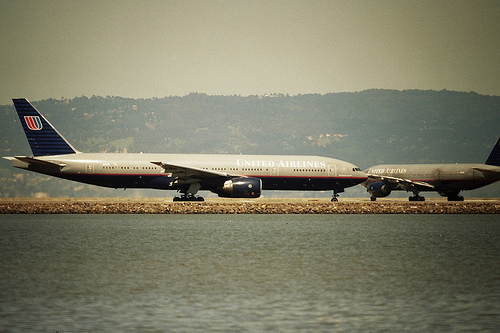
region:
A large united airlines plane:
[360, 140, 497, 200]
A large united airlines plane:
[1, 96, 367, 204]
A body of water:
[3, 211, 496, 331]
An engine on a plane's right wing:
[218, 175, 262, 200]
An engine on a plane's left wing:
[367, 177, 389, 200]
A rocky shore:
[2, 200, 499, 212]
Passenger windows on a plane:
[99, 163, 329, 173]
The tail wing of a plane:
[1, 99, 81, 191]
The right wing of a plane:
[151, 161, 245, 192]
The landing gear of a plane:
[169, 193, 339, 202]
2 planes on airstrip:
[3, 67, 491, 276]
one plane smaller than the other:
[0, 65, 492, 242]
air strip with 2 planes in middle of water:
[2, 3, 499, 261]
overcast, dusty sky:
[1, 0, 496, 200]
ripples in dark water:
[1, 203, 475, 330]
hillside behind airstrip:
[3, 63, 487, 195]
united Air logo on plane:
[16, 98, 91, 173]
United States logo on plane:
[369, 153, 422, 190]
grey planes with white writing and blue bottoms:
[3, 65, 498, 282]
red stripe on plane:
[0, 68, 373, 242]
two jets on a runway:
[5, 67, 485, 242]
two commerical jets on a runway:
[0, 85, 491, 210]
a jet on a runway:
[0, 88, 367, 206]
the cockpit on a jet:
[346, 160, 361, 176]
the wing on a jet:
[147, 160, 250, 177]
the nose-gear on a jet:
[326, 185, 348, 202]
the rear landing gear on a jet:
[167, 181, 207, 203]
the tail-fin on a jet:
[6, 91, 81, 153]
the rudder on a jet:
[15, 105, 35, 153]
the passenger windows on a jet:
[288, 165, 332, 175]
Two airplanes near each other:
[3, 95, 498, 207]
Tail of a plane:
[10, 93, 77, 155]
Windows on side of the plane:
[291, 160, 326, 177]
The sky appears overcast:
[1, 0, 497, 98]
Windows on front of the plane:
[349, 160, 363, 180]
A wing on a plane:
[150, 153, 230, 194]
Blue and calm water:
[1, 212, 499, 330]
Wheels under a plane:
[164, 190, 206, 209]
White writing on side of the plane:
[363, 162, 411, 182]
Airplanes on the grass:
[1, 183, 499, 214]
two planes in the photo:
[23, 90, 490, 257]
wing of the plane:
[151, 145, 235, 204]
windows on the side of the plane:
[233, 160, 338, 179]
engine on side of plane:
[221, 168, 268, 213]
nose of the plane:
[335, 148, 380, 202]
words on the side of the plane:
[231, 158, 333, 174]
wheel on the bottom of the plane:
[325, 190, 345, 209]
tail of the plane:
[3, 83, 91, 182]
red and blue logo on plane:
[21, 111, 45, 138]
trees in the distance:
[311, 85, 406, 139]